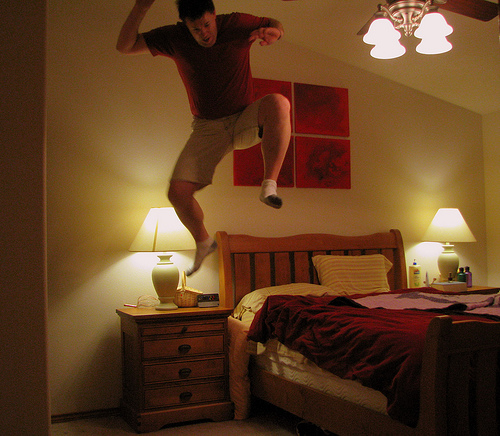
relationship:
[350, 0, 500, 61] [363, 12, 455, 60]
ceiling fan has lights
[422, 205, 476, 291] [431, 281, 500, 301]
lamp on nightstand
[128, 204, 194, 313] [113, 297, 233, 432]
lamp on nightstand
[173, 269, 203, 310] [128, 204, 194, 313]
basket next to lamp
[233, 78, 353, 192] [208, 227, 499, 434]
picture above bed frame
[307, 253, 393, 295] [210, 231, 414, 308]
pillow leaning on headboard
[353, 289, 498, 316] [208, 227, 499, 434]
blanket on bed frame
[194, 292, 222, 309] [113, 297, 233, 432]
alarm clock on nightstand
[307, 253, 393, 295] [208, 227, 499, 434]
pillow on bed frame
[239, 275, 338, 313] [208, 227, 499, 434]
pillow on bed frame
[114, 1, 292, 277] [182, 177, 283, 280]
man wearing socks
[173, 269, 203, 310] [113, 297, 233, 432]
basket on nightstand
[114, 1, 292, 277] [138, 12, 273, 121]
man wearing shirt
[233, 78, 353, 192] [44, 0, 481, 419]
picture on wall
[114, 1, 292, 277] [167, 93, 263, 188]
man wearing shorts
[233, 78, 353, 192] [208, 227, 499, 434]
picture over bed frame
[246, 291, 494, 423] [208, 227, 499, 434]
blanket on bed frame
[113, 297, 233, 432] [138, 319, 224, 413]
nightstand has drawers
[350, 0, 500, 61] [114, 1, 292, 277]
ceiling fan near man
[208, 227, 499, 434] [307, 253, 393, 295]
bed frame has pillow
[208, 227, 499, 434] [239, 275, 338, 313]
bed frame has pillow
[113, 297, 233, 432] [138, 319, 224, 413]
nightstand has 4 drawers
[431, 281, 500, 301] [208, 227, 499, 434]
nightstand next to bed frame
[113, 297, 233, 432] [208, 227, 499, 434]
nightstand next to bed frame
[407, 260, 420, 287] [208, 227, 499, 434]
lotion next to bed frame